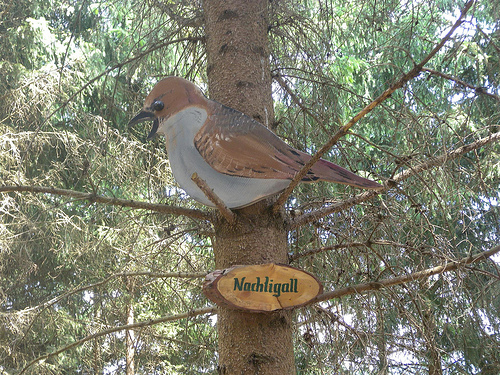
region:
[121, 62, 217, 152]
Fake bird head beak open.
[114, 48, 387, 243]
Fake brown bird in a tree looks upset.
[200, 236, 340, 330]
A sign that is in a tree says nachligall.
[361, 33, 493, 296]
Old pine tree in a sunny tree.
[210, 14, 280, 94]
Sap dripping from the tree down.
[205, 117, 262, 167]
Brown wood painted to show detail.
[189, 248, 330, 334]
Sign made from a wood cut from a tree.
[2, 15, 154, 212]
Pine tree with sun light coming through.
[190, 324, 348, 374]
Tree base with brown sap on it.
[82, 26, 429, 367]
Fake bird in a tree with sign.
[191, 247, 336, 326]
a plastic wood sign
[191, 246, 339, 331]
a woodlike name sign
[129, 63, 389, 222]
a wooden bird in a tree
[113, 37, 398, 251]
a brown wooden bird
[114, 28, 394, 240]
brown wooden bird with white stomach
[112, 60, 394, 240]
an angry wooden bird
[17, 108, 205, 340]
dried up tree branches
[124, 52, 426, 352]
a wooden bird and name plate on a tree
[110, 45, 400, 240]
a fake bird in a tree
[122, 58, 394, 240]
wooden bird perched in tree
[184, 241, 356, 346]
This is a writting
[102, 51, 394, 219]
This is a bird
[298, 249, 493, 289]
This is a branch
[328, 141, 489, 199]
This is a branch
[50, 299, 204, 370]
This is a branch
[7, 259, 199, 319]
This is a branch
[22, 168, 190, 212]
This is a branch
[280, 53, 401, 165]
This is a branch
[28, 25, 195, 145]
This is a branch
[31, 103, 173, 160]
This is a branch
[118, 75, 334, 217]
wood bird carving in the tree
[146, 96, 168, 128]
black beady eyes on the wood carving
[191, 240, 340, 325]
wood slice decor in the tree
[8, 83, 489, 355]
thin branches on the tree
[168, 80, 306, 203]
bird sculpture is painted brown and black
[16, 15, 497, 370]
green pine trees in the background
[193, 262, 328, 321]
sign says nachligall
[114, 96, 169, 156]
bird looks angry with mouth open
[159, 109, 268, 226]
bird has white belly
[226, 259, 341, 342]
writing on sign is green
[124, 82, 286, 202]
wooden bird in tree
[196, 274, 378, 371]
wooden sign in tree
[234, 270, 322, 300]
green letters on sign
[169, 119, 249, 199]
white paint on bird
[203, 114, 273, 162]
brown paint on bird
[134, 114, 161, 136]
black paint on bird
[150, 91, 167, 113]
black eye on bird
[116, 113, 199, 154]
black beak on bird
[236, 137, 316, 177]
brown feathers on bird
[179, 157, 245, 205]
white belly on bird